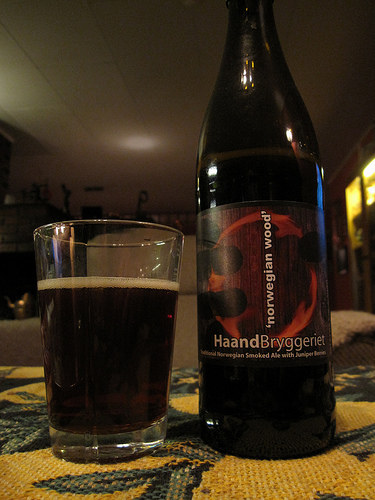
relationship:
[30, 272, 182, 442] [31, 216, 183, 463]
ale in cup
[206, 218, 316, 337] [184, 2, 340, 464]
berries on bottle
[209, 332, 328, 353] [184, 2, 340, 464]
haandbryggeriet on bottle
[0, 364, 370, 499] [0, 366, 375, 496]
floral design on cloth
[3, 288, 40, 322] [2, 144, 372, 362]
tea kettle in background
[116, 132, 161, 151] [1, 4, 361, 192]
light on ceiling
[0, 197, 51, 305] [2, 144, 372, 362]
fireplace in background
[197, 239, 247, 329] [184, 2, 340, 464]
berry on bottle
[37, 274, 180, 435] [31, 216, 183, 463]
ale in cup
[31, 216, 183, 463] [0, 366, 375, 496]
cup on cloth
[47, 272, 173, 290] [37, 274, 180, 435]
head on ale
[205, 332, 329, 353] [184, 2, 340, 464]
writing on bottle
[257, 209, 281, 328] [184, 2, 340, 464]
writing on bottle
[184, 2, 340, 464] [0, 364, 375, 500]
bottle on table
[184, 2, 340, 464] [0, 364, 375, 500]
bottle sitting on table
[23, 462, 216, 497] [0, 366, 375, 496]
coloring on cloth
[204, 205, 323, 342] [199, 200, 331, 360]
coloring on bottle label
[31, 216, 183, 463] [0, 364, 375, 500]
cup sitting on table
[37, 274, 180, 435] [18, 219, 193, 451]
ale in a glass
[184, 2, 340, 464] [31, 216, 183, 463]
bottle next to cup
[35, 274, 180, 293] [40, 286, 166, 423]
foam on top of liquid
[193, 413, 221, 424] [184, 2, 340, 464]
glare on bottle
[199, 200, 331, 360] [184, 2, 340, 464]
bottle label around bottle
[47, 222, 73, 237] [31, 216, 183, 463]
glare on cup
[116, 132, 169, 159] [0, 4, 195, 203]
light shining on ceiling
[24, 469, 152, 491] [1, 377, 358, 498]
leaf on background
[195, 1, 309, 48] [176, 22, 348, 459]
neck of bottle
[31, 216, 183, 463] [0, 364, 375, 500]
cup on table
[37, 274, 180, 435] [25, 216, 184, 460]
ale in cup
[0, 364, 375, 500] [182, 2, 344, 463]
table beneath ale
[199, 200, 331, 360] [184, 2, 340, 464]
bottle label on bottle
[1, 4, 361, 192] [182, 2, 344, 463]
ceiling above ale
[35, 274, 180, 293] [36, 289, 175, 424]
foam of ale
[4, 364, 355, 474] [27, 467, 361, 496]
table has cloth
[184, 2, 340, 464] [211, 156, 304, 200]
bottle contains ale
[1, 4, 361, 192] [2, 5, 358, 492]
ceiling in room